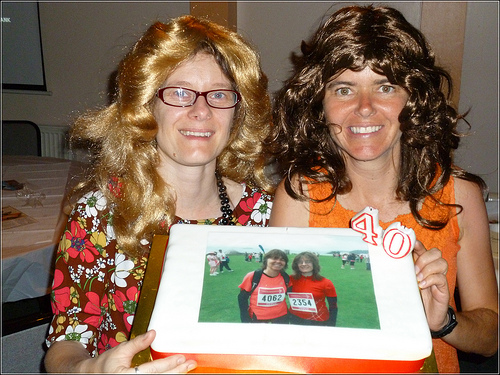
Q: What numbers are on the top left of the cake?
A: 40.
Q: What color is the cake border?
A: Orange.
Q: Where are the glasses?
A: On the woman on the left.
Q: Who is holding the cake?
A: Women.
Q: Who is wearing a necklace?
A: The woman on the left.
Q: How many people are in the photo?
A: 4.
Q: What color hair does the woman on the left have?
A: Brown.